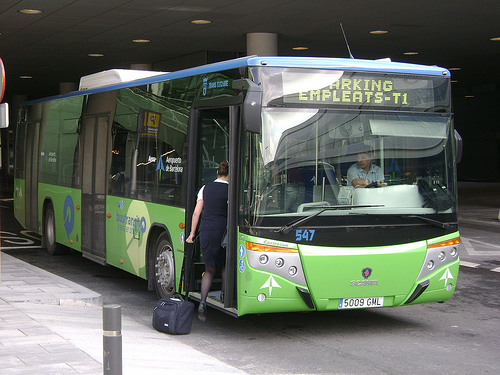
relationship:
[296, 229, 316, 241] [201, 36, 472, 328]
number on bus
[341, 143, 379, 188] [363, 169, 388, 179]
driver sitting at wheel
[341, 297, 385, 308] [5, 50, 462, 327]
license plate on bus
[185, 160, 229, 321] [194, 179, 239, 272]
woman wearing black dress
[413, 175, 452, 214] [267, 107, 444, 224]
backpack by window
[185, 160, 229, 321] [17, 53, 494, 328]
woman gets on bus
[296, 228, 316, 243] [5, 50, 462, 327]
number on bus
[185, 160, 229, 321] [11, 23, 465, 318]
woman stepping on bus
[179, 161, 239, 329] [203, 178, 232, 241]
woman has vest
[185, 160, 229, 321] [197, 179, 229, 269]
woman has black dress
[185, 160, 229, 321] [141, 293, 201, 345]
woman has bag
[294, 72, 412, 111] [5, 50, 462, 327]
lcd screen on bus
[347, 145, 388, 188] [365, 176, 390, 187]
driver behind wheel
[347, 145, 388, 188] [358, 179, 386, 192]
driver behind wheel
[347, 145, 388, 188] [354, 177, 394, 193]
driver behind wheel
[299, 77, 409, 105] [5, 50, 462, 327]
lcd screen in front of bus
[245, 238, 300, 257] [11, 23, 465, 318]
turn signal on bus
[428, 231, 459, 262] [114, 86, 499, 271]
signal on bus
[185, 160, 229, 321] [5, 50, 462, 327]
woman pulling bag on bus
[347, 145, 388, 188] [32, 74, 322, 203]
driver sitting on a bus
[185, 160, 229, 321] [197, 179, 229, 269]
woman wearing a black dress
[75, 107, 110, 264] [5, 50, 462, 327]
doors in center of bus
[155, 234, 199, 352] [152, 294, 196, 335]
bag of bag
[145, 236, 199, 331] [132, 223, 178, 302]
wheel in front of a bus